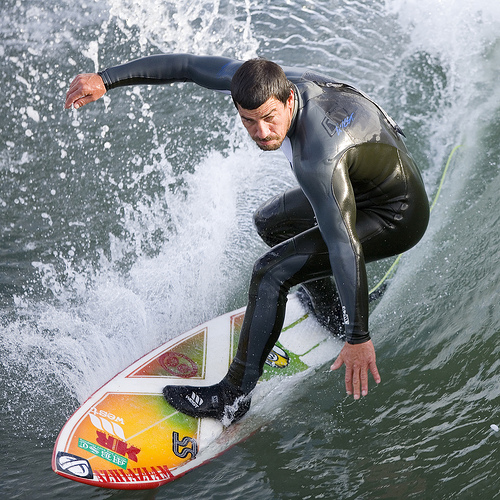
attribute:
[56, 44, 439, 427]
man — surfing, foreground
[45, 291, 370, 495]
surfboard — colorful, multi colored, multicolored, pointy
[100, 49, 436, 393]
wet suit — grey, black, gray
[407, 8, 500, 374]
waves — green, white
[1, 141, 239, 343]
waves — green, white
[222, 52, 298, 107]
dark hair — short, wet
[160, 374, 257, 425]
shoe — black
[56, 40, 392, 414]
arms — stretched out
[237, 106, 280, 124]
eyebrows — dark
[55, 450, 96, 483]
logo — blue, white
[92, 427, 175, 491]
writing — red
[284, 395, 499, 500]
water — green